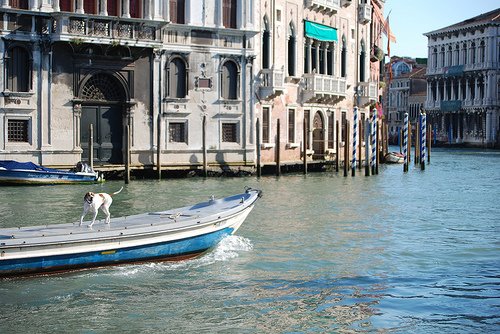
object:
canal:
[0, 143, 499, 333]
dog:
[77, 185, 125, 227]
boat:
[0, 185, 264, 279]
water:
[0, 173, 499, 333]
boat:
[0, 159, 106, 186]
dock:
[0, 159, 319, 176]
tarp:
[0, 160, 78, 173]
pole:
[351, 104, 356, 177]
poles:
[255, 117, 261, 178]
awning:
[303, 21, 338, 42]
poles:
[123, 123, 130, 184]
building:
[0, 0, 386, 180]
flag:
[378, 17, 396, 44]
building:
[384, 8, 499, 149]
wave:
[212, 232, 257, 259]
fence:
[87, 107, 431, 183]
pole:
[302, 118, 308, 176]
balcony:
[297, 73, 347, 105]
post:
[401, 112, 409, 173]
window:
[217, 60, 238, 100]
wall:
[157, 24, 260, 162]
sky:
[382, 0, 499, 64]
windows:
[221, 0, 237, 29]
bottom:
[0, 244, 236, 279]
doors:
[80, 104, 98, 166]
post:
[275, 118, 283, 178]